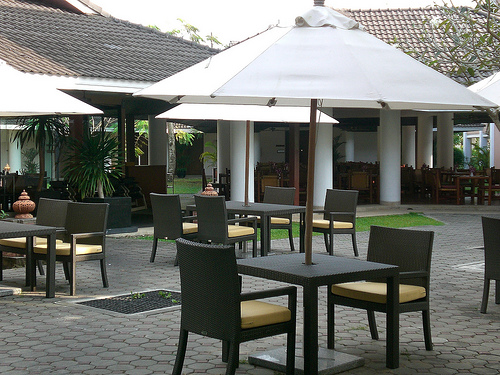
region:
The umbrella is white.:
[205, 37, 457, 123]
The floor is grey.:
[41, 329, 148, 372]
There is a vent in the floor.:
[66, 277, 191, 337]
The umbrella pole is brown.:
[296, 106, 337, 272]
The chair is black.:
[153, 242, 305, 373]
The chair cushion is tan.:
[236, 285, 294, 352]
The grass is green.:
[363, 213, 432, 225]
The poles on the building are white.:
[221, 124, 416, 186]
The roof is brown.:
[46, 19, 193, 64]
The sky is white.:
[175, 12, 290, 39]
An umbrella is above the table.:
[126, 0, 491, 122]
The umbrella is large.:
[119, 1, 491, 116]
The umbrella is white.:
[125, 1, 492, 109]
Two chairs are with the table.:
[159, 211, 451, 373]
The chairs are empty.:
[160, 207, 442, 374]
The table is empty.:
[222, 243, 399, 307]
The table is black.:
[225, 230, 395, 295]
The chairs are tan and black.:
[157, 209, 453, 372]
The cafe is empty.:
[0, 147, 497, 374]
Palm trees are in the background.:
[15, 105, 127, 212]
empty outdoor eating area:
[6, 62, 489, 348]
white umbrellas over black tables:
[20, 30, 467, 335]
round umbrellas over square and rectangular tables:
[25, 16, 430, 348]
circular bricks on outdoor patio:
[11, 225, 212, 370]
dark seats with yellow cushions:
[166, 201, 451, 362]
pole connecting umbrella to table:
[280, 51, 330, 297]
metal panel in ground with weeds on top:
[65, 267, 200, 327]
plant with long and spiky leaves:
[45, 125, 140, 210]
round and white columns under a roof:
[200, 0, 480, 225]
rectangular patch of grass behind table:
[137, 186, 449, 244]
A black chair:
[346, 214, 437, 339]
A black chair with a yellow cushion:
[344, 215, 452, 351]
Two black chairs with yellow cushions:
[152, 237, 457, 365]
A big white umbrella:
[153, 7, 497, 175]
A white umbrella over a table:
[141, 44, 412, 324]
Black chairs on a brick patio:
[8, 188, 464, 364]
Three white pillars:
[211, 130, 421, 210]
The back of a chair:
[365, 233, 443, 278]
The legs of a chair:
[319, 302, 433, 354]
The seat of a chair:
[242, 297, 297, 333]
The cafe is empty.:
[1, 93, 497, 371]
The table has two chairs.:
[172, 206, 450, 373]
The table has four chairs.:
[142, 172, 365, 256]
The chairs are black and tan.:
[165, 212, 450, 369]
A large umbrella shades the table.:
[122, 2, 488, 117]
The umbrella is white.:
[127, 2, 489, 113]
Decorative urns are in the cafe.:
[4, 185, 46, 229]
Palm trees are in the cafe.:
[17, 107, 134, 207]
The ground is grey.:
[0, 315, 168, 373]